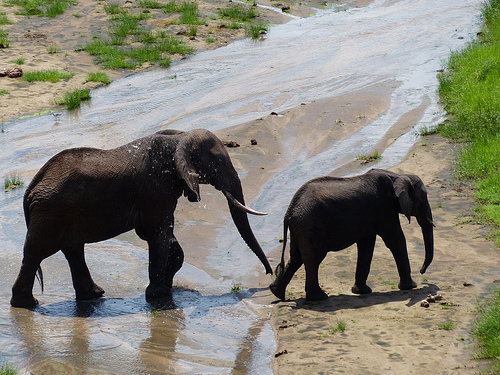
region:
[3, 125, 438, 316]
Two elephants walking in a stream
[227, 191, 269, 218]
Tusks on an elephant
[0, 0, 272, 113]
Grass growing in sand next to a stream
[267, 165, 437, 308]
Baby elephant next to a stream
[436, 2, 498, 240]
Grass growing next to a stream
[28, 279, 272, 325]
Shadow of the elephant in the water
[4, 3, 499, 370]
shallow river of water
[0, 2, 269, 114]
patches of green grass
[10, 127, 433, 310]
sideview of two walking elephants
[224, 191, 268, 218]
white curved ivory tusk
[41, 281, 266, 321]
shadow of adult elephant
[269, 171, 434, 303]
young elephant walking on dirt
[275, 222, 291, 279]
tail on back of elephant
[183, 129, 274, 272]
trunk on elephant head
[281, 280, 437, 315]
shadow of elephant on dirt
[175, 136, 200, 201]
ear of adult elephant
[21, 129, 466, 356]
two elephants are walking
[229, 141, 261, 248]
elephant has white tusks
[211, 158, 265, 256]
elephant has long trunk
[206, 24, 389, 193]
ground is light brown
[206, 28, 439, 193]
water flowing on ground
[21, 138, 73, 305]
elephant has long tail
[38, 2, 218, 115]
green grass on bank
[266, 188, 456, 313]
young elephant in front of parent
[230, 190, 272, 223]
long white ivory tusk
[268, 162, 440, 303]
small elephant in front of large elephant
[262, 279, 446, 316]
shadow of small elephant on ground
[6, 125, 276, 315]
large dark elephant in water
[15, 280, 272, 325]
shadow of large elephant on water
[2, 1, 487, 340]
shallow river of clear water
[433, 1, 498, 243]
thick dense green vegatation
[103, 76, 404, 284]
island of dirt in middle of river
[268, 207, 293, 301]
long silouetted elephant tail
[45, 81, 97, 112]
tuft of green grass on edge of river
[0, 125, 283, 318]
a large elephant walking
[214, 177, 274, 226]
a large elephant's right tusk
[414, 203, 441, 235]
a small elephant's right tusk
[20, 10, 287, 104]
a patch of grass and weeds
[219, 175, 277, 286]
a large elephant's trunk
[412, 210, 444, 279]
a small elephant's trunk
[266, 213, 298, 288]
a small elephant's tail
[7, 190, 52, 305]
a large elephant's tail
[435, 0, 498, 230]
a grassy area on the right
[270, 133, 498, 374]
a sandy area by the stream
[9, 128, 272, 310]
an elephant crossing the stream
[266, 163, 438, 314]
An animal in a field.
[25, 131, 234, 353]
An animal in a field.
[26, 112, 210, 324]
A large grey elephant.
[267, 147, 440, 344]
A large grey elephant.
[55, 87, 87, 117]
A patch of grass.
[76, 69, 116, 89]
A patch of grass.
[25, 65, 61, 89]
A patch of grass.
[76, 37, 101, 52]
A patch of grass.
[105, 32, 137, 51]
A patch of grass.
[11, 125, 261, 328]
A large grey elephant.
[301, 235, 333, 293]
The limb of an animal.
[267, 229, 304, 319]
The limb of an animal.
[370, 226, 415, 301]
The limb of an animal.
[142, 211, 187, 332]
The limb of an animal.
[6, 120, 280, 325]
tall grey colored elephant